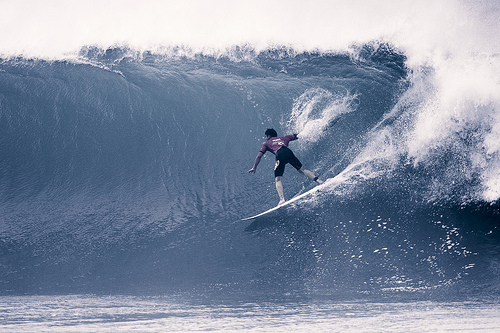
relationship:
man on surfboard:
[245, 120, 320, 212] [229, 175, 352, 224]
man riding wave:
[245, 127, 324, 205] [260, 39, 491, 279]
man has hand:
[245, 127, 324, 205] [246, 167, 257, 173]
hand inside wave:
[246, 167, 257, 173] [29, 48, 485, 225]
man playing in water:
[245, 127, 324, 205] [0, 52, 498, 332]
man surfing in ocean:
[245, 127, 324, 205] [31, 16, 481, 261]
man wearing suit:
[245, 127, 324, 205] [259, 130, 313, 188]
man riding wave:
[245, 127, 324, 205] [0, 18, 500, 196]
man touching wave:
[245, 127, 324, 205] [339, 73, 475, 220]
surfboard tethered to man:
[243, 176, 334, 220] [245, 127, 324, 205]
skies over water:
[29, 9, 306, 59] [0, 27, 498, 333]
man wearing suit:
[245, 127, 324, 205] [257, 133, 305, 178]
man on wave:
[245, 127, 324, 205] [0, 12, 498, 326]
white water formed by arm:
[289, 87, 357, 143] [232, 148, 282, 171]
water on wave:
[0, 27, 498, 333] [305, 99, 495, 272]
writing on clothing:
[273, 136, 283, 144] [258, 130, 300, 176]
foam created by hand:
[291, 82, 360, 155] [296, 131, 301, 137]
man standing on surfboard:
[245, 127, 324, 205] [239, 176, 334, 221]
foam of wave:
[19, 31, 498, 94] [7, 52, 487, 331]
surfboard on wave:
[239, 176, 334, 221] [70, 59, 195, 265]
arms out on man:
[244, 129, 304, 178] [245, 127, 324, 205]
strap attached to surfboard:
[307, 170, 322, 190] [239, 176, 334, 221]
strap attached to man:
[307, 170, 322, 190] [248, 125, 327, 213]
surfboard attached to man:
[239, 176, 334, 221] [248, 125, 327, 213]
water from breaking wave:
[112, 142, 227, 253] [398, 65, 471, 152]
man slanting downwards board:
[245, 127, 324, 205] [241, 176, 341, 227]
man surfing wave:
[245, 127, 324, 205] [299, 82, 444, 167]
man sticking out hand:
[245, 127, 324, 205] [279, 133, 300, 143]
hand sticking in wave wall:
[279, 133, 300, 143] [3, 40, 419, 197]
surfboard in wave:
[239, 176, 334, 221] [9, 23, 498, 275]